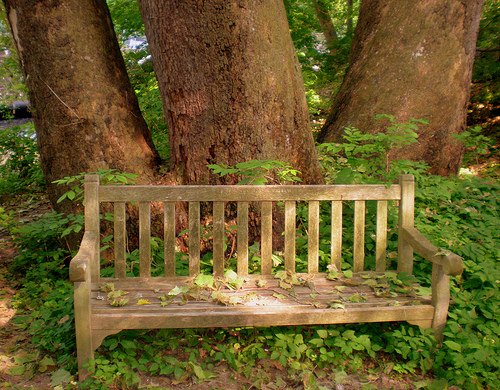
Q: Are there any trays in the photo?
A: No, there are no trays.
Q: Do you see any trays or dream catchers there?
A: No, there are no trays or dream catchers.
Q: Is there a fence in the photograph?
A: No, there are no fences.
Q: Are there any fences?
A: No, there are no fences.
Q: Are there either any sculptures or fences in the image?
A: No, there are no fences or sculptures.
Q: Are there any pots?
A: No, there are no pots.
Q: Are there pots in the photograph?
A: No, there are no pots.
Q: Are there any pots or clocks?
A: No, there are no pots or clocks.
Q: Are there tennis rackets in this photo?
A: No, there are no tennis rackets.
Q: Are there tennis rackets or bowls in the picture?
A: No, there are no tennis rackets or bowls.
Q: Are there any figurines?
A: No, there are no figurines.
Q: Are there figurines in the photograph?
A: No, there are no figurines.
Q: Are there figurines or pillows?
A: No, there are no figurines or pillows.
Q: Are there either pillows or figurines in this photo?
A: No, there are no figurines or pillows.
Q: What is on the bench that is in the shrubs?
A: The leaves are on the bench.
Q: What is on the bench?
A: The leaves are on the bench.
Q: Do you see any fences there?
A: No, there are no fences.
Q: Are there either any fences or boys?
A: No, there are no fences or boys.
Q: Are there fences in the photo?
A: No, there are no fences.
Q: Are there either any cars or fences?
A: No, there are no fences or cars.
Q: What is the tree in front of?
A: The tree is in front of the shrubs.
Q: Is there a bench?
A: Yes, there is a bench.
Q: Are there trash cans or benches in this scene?
A: Yes, there is a bench.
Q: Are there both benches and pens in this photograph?
A: No, there is a bench but no pens.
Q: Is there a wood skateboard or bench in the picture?
A: Yes, there is a wood bench.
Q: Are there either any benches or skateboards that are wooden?
A: Yes, the bench is wooden.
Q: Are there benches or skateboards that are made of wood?
A: Yes, the bench is made of wood.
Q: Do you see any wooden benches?
A: Yes, there is a wood bench.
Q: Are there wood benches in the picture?
A: Yes, there is a wood bench.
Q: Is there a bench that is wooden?
A: Yes, there is a bench that is wooden.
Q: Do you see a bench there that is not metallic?
A: Yes, there is a wooden bench.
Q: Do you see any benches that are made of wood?
A: Yes, there is a bench that is made of wood.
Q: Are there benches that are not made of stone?
A: Yes, there is a bench that is made of wood.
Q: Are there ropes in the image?
A: No, there are no ropes.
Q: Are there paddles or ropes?
A: No, there are no ropes or paddles.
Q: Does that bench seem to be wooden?
A: Yes, the bench is wooden.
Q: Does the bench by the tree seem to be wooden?
A: Yes, the bench is wooden.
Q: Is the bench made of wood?
A: Yes, the bench is made of wood.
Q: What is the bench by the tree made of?
A: The bench is made of wood.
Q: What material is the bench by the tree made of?
A: The bench is made of wood.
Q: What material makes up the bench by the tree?
A: The bench is made of wood.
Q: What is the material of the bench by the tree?
A: The bench is made of wood.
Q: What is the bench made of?
A: The bench is made of wood.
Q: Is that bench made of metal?
A: No, the bench is made of wood.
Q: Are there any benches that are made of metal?
A: No, there is a bench but it is made of wood.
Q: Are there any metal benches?
A: No, there is a bench but it is made of wood.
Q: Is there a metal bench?
A: No, there is a bench but it is made of wood.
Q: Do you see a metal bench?
A: No, there is a bench but it is made of wood.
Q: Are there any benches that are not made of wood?
A: No, there is a bench but it is made of wood.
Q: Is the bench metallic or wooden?
A: The bench is wooden.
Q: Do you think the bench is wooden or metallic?
A: The bench is wooden.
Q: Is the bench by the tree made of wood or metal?
A: The bench is made of wood.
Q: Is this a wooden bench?
A: Yes, this is a wooden bench.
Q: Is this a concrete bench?
A: No, this is a wooden bench.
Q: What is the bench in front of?
A: The bench is in front of the plant.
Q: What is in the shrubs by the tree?
A: The bench is in the bushes.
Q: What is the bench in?
A: The bench is in the shrubs.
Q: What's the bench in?
A: The bench is in the shrubs.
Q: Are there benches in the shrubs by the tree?
A: Yes, there is a bench in the bushes.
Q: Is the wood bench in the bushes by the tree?
A: Yes, the bench is in the shrubs.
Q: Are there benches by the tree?
A: Yes, there is a bench by the tree.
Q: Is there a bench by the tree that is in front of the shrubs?
A: Yes, there is a bench by the tree.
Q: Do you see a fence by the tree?
A: No, there is a bench by the tree.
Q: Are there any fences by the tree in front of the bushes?
A: No, there is a bench by the tree.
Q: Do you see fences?
A: No, there are no fences.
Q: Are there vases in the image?
A: No, there are no vases.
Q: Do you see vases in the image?
A: No, there are no vases.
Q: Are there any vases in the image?
A: No, there are no vases.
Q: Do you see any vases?
A: No, there are no vases.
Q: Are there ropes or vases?
A: No, there are no vases or ropes.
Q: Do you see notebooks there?
A: No, there are no notebooks.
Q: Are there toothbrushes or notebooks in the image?
A: No, there are no notebooks or toothbrushes.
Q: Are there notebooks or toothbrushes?
A: No, there are no notebooks or toothbrushes.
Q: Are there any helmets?
A: No, there are no helmets.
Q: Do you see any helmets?
A: No, there are no helmets.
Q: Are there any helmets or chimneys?
A: No, there are no helmets or chimneys.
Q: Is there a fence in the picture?
A: No, there are no fences.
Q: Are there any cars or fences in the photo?
A: No, there are no fences or cars.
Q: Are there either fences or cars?
A: No, there are no fences or cars.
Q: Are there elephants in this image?
A: No, there are no elephants.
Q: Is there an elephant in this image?
A: No, there are no elephants.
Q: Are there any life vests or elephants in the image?
A: No, there are no elephants or life vests.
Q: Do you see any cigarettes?
A: No, there are no cigarettes.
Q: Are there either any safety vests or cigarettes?
A: No, there are no cigarettes or safety vests.